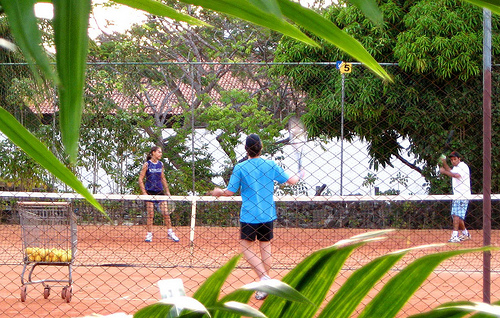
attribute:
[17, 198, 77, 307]
cart — grocery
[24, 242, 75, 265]
balls — yellow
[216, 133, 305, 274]
person — swining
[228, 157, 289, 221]
shirt — blue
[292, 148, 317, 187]
racket — moving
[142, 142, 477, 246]
people — playing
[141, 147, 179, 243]
girl — playing, looking, standing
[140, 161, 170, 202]
shirt — purple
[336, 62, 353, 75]
sigh — yellow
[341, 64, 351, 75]
number — 5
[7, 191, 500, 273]
net — dark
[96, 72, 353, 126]
fence — chain linked, chainlinked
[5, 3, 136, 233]
plant — green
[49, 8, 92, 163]
leaves — large, long, green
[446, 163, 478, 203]
shirt — white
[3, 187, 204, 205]
top — white